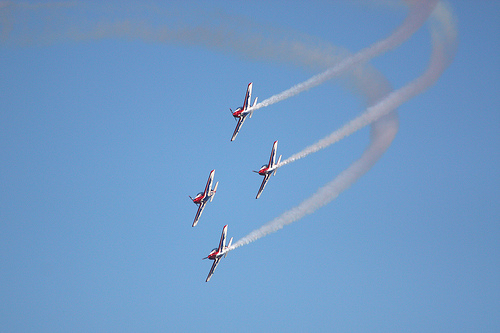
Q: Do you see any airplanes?
A: Yes, there is an airplane.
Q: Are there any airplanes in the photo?
A: Yes, there is an airplane.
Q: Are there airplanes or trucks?
A: Yes, there is an airplane.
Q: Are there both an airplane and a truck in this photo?
A: No, there is an airplane but no trucks.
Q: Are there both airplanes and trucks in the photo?
A: No, there is an airplane but no trucks.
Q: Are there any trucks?
A: No, there are no trucks.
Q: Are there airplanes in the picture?
A: Yes, there is an airplane.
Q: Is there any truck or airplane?
A: Yes, there is an airplane.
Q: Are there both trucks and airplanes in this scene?
A: No, there is an airplane but no trucks.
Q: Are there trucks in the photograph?
A: No, there are no trucks.